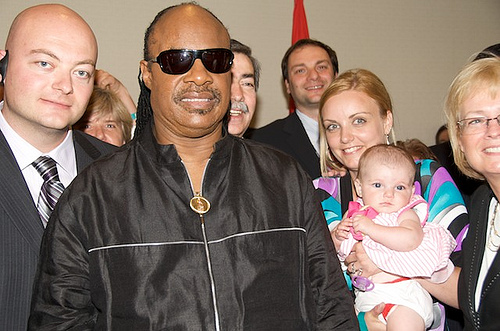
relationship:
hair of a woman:
[441, 60, 499, 174] [445, 54, 498, 329]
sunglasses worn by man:
[132, 26, 269, 75] [93, 12, 286, 328]